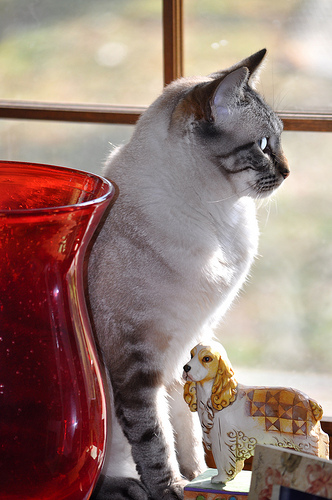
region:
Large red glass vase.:
[1, 151, 108, 499]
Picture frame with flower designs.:
[243, 443, 331, 498]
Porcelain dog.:
[187, 337, 329, 449]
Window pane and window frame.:
[30, 16, 195, 152]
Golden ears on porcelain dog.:
[209, 354, 238, 411]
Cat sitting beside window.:
[122, 51, 302, 321]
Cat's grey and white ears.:
[187, 49, 294, 132]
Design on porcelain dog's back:
[251, 380, 326, 435]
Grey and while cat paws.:
[104, 380, 195, 496]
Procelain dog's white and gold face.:
[178, 340, 228, 406]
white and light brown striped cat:
[85, 46, 289, 499]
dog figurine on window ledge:
[182, 340, 331, 499]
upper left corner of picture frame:
[247, 442, 330, 499]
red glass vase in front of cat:
[0, 162, 119, 498]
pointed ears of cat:
[207, 47, 268, 119]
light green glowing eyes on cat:
[259, 136, 268, 152]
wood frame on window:
[159, 0, 187, 77]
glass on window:
[1, 0, 164, 107]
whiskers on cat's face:
[208, 164, 281, 228]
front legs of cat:
[100, 335, 215, 499]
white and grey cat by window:
[84, 45, 298, 499]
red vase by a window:
[2, 143, 124, 496]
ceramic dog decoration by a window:
[181, 331, 322, 498]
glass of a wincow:
[41, 6, 140, 92]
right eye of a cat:
[249, 132, 285, 152]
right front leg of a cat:
[106, 349, 184, 498]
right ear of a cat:
[198, 66, 260, 125]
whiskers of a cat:
[221, 191, 283, 221]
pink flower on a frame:
[300, 458, 329, 498]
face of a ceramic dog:
[180, 334, 230, 386]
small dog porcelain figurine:
[185, 344, 326, 485]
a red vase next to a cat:
[3, 149, 128, 498]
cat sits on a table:
[78, 37, 302, 491]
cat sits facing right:
[95, 36, 329, 262]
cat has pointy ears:
[197, 41, 294, 201]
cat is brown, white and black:
[64, 28, 301, 492]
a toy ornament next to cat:
[177, 331, 330, 496]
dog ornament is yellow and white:
[166, 330, 331, 487]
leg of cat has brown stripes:
[104, 338, 190, 498]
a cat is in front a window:
[3, 18, 330, 428]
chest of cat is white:
[162, 197, 263, 333]